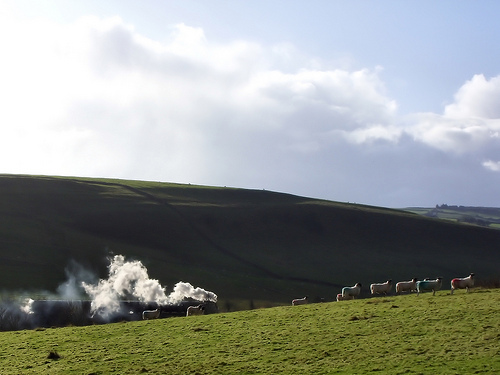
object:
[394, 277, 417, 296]
sheep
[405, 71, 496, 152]
clouds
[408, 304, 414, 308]
green broccoli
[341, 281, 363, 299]
animals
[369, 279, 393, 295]
sheep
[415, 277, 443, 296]
animal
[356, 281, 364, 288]
bleack head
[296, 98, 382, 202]
ground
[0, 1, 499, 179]
sky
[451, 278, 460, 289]
butt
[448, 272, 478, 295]
sheep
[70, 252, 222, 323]
smoke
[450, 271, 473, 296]
sheep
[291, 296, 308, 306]
animal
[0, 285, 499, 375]
field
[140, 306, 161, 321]
animal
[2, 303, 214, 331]
train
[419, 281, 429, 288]
marking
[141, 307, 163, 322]
sheep